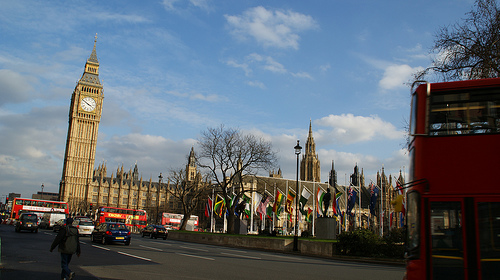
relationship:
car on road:
[90, 220, 141, 251] [131, 247, 224, 272]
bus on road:
[404, 77, 491, 277] [131, 247, 224, 272]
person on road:
[54, 218, 81, 263] [131, 247, 224, 272]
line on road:
[119, 249, 164, 264] [131, 247, 224, 272]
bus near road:
[404, 77, 491, 277] [131, 247, 224, 272]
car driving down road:
[90, 220, 141, 251] [131, 247, 224, 272]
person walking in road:
[54, 218, 81, 263] [131, 247, 224, 272]